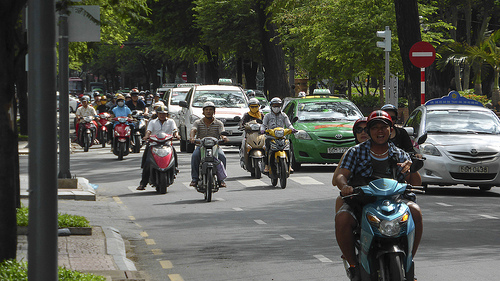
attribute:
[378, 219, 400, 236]
headlight — clear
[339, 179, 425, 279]
motorcycle — aqua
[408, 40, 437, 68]
sign — red, white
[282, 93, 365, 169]
car — green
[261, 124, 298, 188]
motorcycle — mustard yellow, yellow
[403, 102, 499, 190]
car — white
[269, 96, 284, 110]
helmet — white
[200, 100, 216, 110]
helmet — white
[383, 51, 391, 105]
pole — gray, metal, red, white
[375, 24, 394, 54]
light — white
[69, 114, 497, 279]
road — gray, busy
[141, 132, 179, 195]
motorcycle — red, silver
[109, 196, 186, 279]
line — yellow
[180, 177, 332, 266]
line — yellow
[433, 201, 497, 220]
line — yellow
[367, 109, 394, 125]
helmet — red, black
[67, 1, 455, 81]
leaves — green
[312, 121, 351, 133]
graphic — orange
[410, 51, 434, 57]
line — white